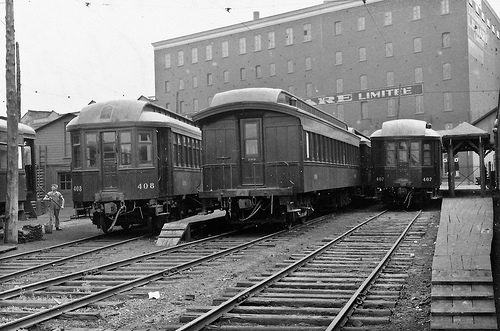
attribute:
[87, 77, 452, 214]
cars — Train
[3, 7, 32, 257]
pole — large, wooden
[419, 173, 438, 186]
407 — white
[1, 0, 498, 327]
photo — black, white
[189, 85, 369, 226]
container — black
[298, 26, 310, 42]
window pane — missing